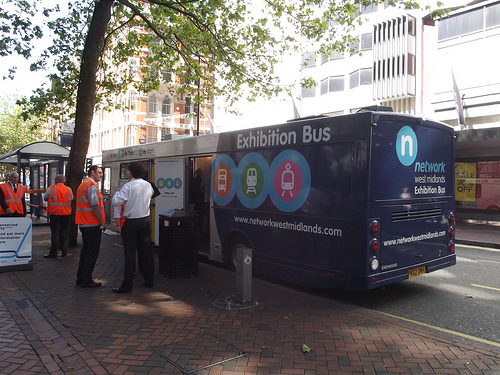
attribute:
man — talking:
[73, 165, 105, 287]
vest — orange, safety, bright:
[71, 176, 104, 227]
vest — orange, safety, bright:
[49, 184, 73, 215]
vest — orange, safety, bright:
[0, 180, 27, 212]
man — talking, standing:
[116, 166, 157, 294]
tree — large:
[55, 3, 114, 250]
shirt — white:
[114, 176, 157, 219]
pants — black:
[123, 221, 154, 290]